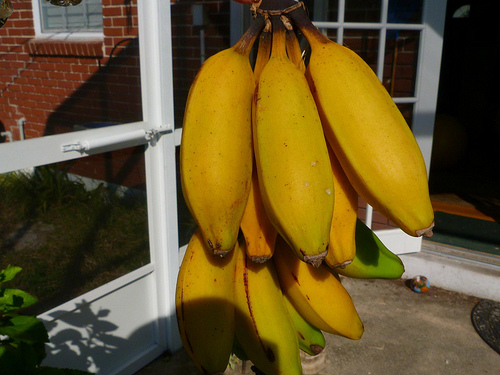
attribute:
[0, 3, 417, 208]
brick wall — red 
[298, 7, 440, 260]
door — open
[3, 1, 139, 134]
casing — brick